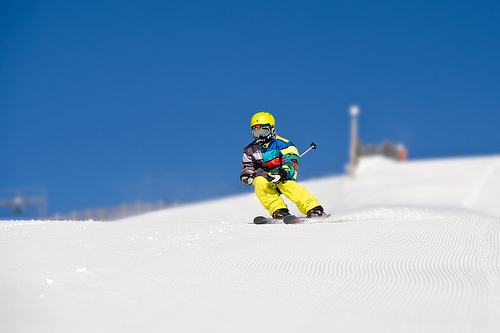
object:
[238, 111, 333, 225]
skier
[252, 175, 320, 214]
pants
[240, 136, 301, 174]
jacket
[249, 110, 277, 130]
helmet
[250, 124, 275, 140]
goggles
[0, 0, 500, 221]
sky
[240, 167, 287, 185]
gloves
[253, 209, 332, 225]
skiboards